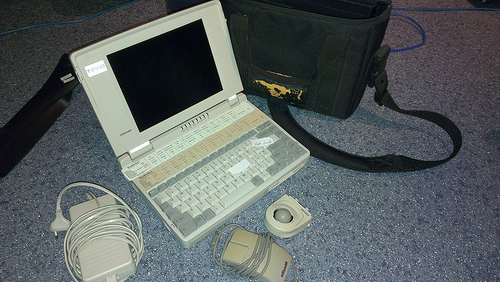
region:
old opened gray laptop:
[62, 3, 321, 252]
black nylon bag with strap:
[259, 3, 472, 172]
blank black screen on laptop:
[110, 13, 220, 133]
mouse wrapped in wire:
[213, 224, 294, 280]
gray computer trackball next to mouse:
[247, 193, 311, 256]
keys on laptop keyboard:
[185, 153, 262, 203]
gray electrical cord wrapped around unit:
[44, 198, 131, 260]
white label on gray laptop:
[80, 52, 114, 84]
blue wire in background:
[399, 5, 456, 55]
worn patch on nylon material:
[240, 65, 313, 108]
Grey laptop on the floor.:
[63, 37, 340, 199]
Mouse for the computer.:
[202, 225, 300, 280]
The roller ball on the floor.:
[256, 190, 311, 230]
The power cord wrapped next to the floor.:
[65, 185, 135, 271]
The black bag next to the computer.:
[190, 10, 415, 120]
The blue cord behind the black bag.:
[386, 15, 451, 60]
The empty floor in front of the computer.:
[340, 185, 485, 275]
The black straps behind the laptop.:
[7, 75, 101, 142]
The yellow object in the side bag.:
[235, 60, 320, 105]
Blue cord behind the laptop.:
[12, 13, 136, 35]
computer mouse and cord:
[215, 228, 298, 278]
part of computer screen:
[115, 20, 218, 115]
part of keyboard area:
[156, 137, 273, 202]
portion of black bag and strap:
[307, 7, 472, 160]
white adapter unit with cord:
[38, 192, 135, 279]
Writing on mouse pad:
[279, 248, 289, 280]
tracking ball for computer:
[263, 197, 315, 231]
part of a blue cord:
[400, 11, 423, 56]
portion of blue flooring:
[352, 223, 486, 270]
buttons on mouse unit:
[230, 227, 251, 264]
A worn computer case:
[241, 60, 316, 105]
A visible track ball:
[260, 200, 315, 232]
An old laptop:
[56, 36, 333, 206]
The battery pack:
[31, 180, 158, 276]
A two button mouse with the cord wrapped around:
[210, 216, 301, 276]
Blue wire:
[380, 1, 460, 56]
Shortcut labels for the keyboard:
[113, 118, 278, 175]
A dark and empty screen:
[110, 5, 220, 135]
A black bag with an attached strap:
[255, 5, 465, 175]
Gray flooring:
[330, 178, 497, 258]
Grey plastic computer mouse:
[193, 179, 328, 280]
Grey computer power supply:
[39, 175, 154, 280]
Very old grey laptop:
[56, 0, 353, 253]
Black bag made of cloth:
[155, 0, 462, 186]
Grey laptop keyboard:
[140, 115, 320, 240]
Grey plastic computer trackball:
[255, 188, 321, 234]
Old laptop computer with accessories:
[11, 5, 336, 280]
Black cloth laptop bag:
[137, 0, 474, 185]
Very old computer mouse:
[197, 219, 302, 280]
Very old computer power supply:
[47, 173, 157, 280]